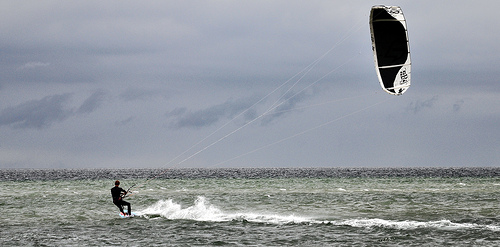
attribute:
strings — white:
[144, 45, 364, 168]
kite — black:
[368, 3, 415, 97]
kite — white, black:
[358, 7, 440, 114]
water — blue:
[1, 167, 498, 245]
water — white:
[177, 187, 234, 231]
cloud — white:
[2, 50, 115, 136]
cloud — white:
[144, 71, 331, 134]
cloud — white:
[387, 75, 492, 126]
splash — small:
[152, 184, 257, 236]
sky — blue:
[61, 15, 351, 151]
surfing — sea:
[119, 199, 180, 221]